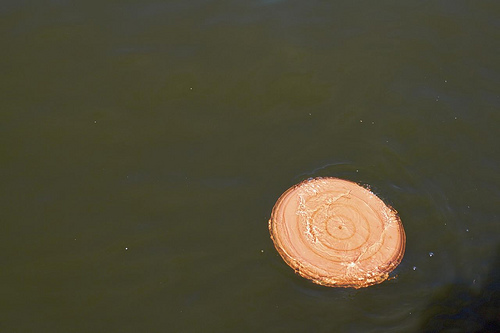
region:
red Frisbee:
[253, 161, 413, 303]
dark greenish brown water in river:
[64, 70, 109, 112]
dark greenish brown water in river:
[127, 205, 182, 257]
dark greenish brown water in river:
[50, 138, 94, 174]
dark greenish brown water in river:
[385, 274, 432, 304]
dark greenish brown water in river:
[386, 103, 417, 127]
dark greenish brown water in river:
[249, 99, 266, 118]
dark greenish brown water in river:
[105, 84, 161, 150]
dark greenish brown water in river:
[92, 229, 145, 269]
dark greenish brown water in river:
[116, 51, 181, 132]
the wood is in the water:
[272, 181, 411, 288]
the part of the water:
[1, 2, 111, 86]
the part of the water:
[116, 0, 241, 80]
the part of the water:
[221, 1, 339, 74]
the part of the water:
[351, 0, 460, 74]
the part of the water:
[1, 81, 88, 169]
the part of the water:
[124, 100, 219, 176]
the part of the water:
[13, 193, 116, 308]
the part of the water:
[131, 195, 231, 317]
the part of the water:
[396, 105, 476, 205]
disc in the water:
[268, 182, 430, 294]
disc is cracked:
[291, 198, 380, 260]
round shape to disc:
[256, 192, 441, 314]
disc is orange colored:
[276, 177, 406, 294]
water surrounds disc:
[8, 68, 250, 315]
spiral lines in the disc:
[297, 201, 382, 266]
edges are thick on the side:
[264, 202, 296, 294]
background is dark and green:
[66, 29, 484, 155]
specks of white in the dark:
[422, 229, 454, 285]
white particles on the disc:
[336, 252, 359, 287]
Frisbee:
[264, 165, 411, 287]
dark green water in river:
[43, 30, 111, 122]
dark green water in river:
[54, 140, 114, 205]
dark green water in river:
[399, 34, 433, 88]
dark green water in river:
[284, 34, 336, 100]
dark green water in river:
[418, 250, 455, 311]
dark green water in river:
[82, 75, 189, 193]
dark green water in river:
[165, 253, 188, 273]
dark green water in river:
[76, 212, 128, 262]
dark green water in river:
[187, 150, 222, 187]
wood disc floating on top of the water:
[267, 173, 410, 288]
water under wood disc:
[1, 1, 498, 331]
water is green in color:
[1, 3, 496, 331]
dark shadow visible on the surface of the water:
[406, 265, 498, 330]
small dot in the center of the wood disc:
[338, 225, 341, 230]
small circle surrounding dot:
[325, 214, 357, 239]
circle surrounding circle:
[311, 202, 371, 250]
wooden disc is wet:
[266, 176, 407, 288]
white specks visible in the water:
[428, 250, 434, 256]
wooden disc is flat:
[268, 173, 406, 288]